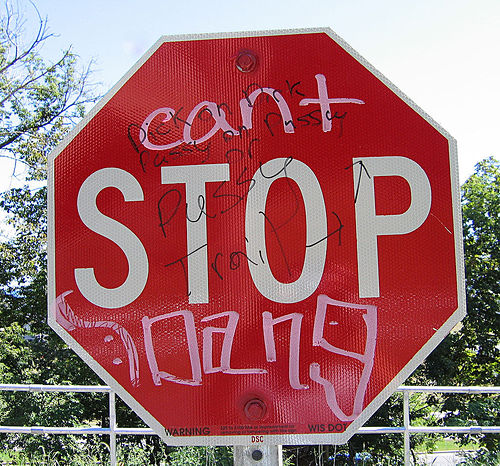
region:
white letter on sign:
[75, 168, 153, 311]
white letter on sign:
[158, 160, 233, 297]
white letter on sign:
[243, 158, 328, 304]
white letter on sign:
[349, 153, 432, 298]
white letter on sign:
[309, 294, 378, 429]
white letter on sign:
[256, 308, 309, 394]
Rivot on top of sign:
[237, 51, 254, 70]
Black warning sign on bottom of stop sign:
[162, 422, 347, 438]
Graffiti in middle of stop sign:
[54, 72, 378, 421]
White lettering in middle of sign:
[73, 156, 432, 308]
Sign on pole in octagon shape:
[46, 26, 467, 446]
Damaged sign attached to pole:
[45, 26, 468, 447]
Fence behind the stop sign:
[1, 382, 499, 464]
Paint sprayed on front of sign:
[55, 294, 378, 419]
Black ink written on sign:
[126, 78, 372, 297]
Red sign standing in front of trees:
[3, 4, 498, 464]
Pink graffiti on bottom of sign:
[58, 288, 378, 422]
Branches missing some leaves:
[0, 0, 107, 181]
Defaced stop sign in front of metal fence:
[46, 26, 469, 446]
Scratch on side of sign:
[429, 211, 451, 236]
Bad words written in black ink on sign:
[118, 78, 373, 297]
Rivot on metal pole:
[251, 449, 262, 459]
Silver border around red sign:
[46, 26, 468, 446]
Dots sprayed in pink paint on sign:
[103, 335, 125, 365]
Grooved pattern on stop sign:
[46, 25, 466, 445]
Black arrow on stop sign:
[343, 157, 371, 204]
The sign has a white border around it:
[11, 15, 457, 462]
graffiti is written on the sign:
[134, 67, 375, 296]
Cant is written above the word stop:
[117, 64, 369, 152]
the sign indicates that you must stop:
[18, 28, 492, 453]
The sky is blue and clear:
[11, 10, 481, 180]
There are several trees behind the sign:
[26, 22, 497, 432]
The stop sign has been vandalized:
[25, 5, 491, 462]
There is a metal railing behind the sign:
[11, 352, 496, 458]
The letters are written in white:
[68, 153, 440, 308]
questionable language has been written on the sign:
[124, 62, 380, 327]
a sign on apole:
[107, 45, 409, 392]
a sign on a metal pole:
[91, 78, 425, 434]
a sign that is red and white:
[49, 44, 466, 422]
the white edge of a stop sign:
[272, 424, 374, 456]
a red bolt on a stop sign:
[240, 395, 281, 425]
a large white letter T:
[151, 145, 242, 316]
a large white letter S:
[52, 161, 163, 316]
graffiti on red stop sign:
[135, 85, 338, 150]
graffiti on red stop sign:
[46, 286, 146, 387]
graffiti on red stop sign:
[135, 295, 375, 427]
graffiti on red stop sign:
[156, 230, 297, 310]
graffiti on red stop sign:
[155, 160, 310, 232]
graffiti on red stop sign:
[127, 132, 213, 170]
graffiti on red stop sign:
[260, 105, 353, 138]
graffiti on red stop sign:
[332, 155, 369, 208]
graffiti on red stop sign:
[299, 200, 347, 255]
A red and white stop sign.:
[35, 33, 496, 461]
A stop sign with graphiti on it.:
[38, 20, 470, 437]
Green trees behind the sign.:
[448, 158, 499, 463]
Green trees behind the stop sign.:
[6, 3, 121, 458]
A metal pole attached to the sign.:
[226, 440, 281, 464]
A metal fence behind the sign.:
[372, 381, 498, 455]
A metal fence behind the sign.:
[1, 374, 126, 456]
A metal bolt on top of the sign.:
[224, 49, 262, 73]